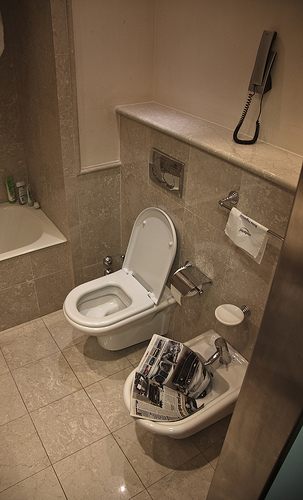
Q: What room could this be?
A: It is a bathroom.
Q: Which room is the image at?
A: It is at the bathroom.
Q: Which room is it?
A: It is a bathroom.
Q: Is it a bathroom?
A: Yes, it is a bathroom.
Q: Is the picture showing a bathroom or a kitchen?
A: It is showing a bathroom.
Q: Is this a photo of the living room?
A: No, the picture is showing the bathroom.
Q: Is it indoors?
A: Yes, it is indoors.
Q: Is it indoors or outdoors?
A: It is indoors.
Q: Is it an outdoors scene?
A: No, it is indoors.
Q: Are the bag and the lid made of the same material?
A: Yes, both the bag and the lid are made of plastic.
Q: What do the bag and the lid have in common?
A: The material, both the bag and the lid are plastic.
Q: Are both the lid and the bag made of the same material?
A: Yes, both the lid and the bag are made of plastic.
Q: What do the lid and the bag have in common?
A: The material, both the lid and the bag are plastic.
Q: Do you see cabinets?
A: No, there are no cabinets.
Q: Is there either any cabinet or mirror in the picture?
A: No, there are no cabinets or mirrors.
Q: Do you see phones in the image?
A: Yes, there is a phone.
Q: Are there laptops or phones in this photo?
A: Yes, there is a phone.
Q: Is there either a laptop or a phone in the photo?
A: Yes, there is a phone.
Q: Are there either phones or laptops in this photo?
A: Yes, there is a phone.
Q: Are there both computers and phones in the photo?
A: No, there is a phone but no computers.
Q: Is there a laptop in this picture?
A: No, there are no laptops.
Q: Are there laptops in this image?
A: No, there are no laptops.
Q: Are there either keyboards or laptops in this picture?
A: No, there are no laptops or keyboards.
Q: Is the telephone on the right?
A: Yes, the telephone is on the right of the image.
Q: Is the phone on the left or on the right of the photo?
A: The phone is on the right of the image.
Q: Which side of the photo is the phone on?
A: The phone is on the right of the image.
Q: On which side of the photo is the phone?
A: The phone is on the right of the image.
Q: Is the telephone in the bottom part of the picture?
A: No, the telephone is in the top of the image.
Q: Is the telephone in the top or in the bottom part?
A: The telephone is in the top of the image.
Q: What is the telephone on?
A: The telephone is on the wall.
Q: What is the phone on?
A: The telephone is on the wall.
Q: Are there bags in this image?
A: Yes, there is a bag.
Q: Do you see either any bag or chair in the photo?
A: Yes, there is a bag.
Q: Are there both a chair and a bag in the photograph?
A: No, there is a bag but no chairs.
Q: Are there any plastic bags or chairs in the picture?
A: Yes, there is a plastic bag.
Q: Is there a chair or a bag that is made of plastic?
A: Yes, the bag is made of plastic.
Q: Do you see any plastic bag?
A: Yes, there is a bag that is made of plastic.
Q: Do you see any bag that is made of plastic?
A: Yes, there is a bag that is made of plastic.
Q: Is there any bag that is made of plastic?
A: Yes, there is a bag that is made of plastic.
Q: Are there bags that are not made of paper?
A: Yes, there is a bag that is made of plastic.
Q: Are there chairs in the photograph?
A: No, there are no chairs.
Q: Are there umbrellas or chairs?
A: No, there are no chairs or umbrellas.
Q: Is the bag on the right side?
A: Yes, the bag is on the right of the image.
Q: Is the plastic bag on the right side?
A: Yes, the bag is on the right of the image.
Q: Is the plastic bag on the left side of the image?
A: No, the bag is on the right of the image.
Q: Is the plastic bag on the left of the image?
A: No, the bag is on the right of the image.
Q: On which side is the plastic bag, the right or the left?
A: The bag is on the right of the image.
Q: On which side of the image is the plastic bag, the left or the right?
A: The bag is on the right of the image.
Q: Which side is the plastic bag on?
A: The bag is on the right of the image.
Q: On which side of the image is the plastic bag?
A: The bag is on the right of the image.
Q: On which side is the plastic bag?
A: The bag is on the right of the image.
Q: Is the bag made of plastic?
A: Yes, the bag is made of plastic.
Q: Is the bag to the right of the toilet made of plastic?
A: Yes, the bag is made of plastic.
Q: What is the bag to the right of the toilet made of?
A: The bag is made of plastic.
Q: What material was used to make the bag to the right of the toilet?
A: The bag is made of plastic.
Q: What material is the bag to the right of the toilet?
A: The bag is made of plastic.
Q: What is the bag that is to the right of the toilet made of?
A: The bag is made of plastic.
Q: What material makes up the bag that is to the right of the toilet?
A: The bag is made of plastic.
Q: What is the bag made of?
A: The bag is made of plastic.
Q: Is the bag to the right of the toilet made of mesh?
A: No, the bag is made of plastic.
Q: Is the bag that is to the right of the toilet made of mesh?
A: No, the bag is made of plastic.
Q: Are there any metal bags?
A: No, there is a bag but it is made of plastic.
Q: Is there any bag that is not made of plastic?
A: No, there is a bag but it is made of plastic.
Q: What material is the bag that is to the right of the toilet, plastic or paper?
A: The bag is made of plastic.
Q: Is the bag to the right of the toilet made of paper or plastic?
A: The bag is made of plastic.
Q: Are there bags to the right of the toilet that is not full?
A: Yes, there is a bag to the right of the toilet.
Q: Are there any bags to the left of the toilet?
A: No, the bag is to the right of the toilet.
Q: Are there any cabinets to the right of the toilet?
A: No, there is a bag to the right of the toilet.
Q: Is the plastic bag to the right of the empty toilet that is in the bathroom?
A: Yes, the bag is to the right of the toilet.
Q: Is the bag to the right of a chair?
A: No, the bag is to the right of the toilet.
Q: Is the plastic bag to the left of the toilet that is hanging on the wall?
A: No, the bag is to the right of the toilet.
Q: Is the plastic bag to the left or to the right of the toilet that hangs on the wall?
A: The bag is to the right of the toilet.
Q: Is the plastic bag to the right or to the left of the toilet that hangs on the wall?
A: The bag is to the right of the toilet.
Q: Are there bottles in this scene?
A: Yes, there is a bottle.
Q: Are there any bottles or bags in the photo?
A: Yes, there is a bottle.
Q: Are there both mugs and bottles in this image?
A: No, there is a bottle but no mugs.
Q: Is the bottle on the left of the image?
A: Yes, the bottle is on the left of the image.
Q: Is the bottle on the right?
A: No, the bottle is on the left of the image.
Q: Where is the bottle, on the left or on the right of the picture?
A: The bottle is on the left of the image.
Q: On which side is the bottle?
A: The bottle is on the left of the image.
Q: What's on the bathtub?
A: The bottle is on the bathtub.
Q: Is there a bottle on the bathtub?
A: Yes, there is a bottle on the bathtub.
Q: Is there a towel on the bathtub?
A: No, there is a bottle on the bathtub.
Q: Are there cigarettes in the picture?
A: No, there are no cigarettes.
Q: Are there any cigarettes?
A: No, there are no cigarettes.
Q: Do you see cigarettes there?
A: No, there are no cigarettes.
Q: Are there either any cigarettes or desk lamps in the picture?
A: No, there are no cigarettes or desk lamps.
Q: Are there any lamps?
A: No, there are no lamps.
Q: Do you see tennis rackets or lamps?
A: No, there are no lamps or tennis rackets.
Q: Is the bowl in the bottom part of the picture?
A: Yes, the bowl is in the bottom of the image.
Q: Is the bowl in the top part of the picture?
A: No, the bowl is in the bottom of the image.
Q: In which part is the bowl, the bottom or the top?
A: The bowl is in the bottom of the image.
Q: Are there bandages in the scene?
A: No, there are no bandages.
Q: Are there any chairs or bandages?
A: No, there are no bandages or chairs.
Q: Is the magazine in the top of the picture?
A: No, the magazine is in the bottom of the image.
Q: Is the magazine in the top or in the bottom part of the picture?
A: The magazine is in the bottom of the image.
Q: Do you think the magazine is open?
A: Yes, the magazine is open.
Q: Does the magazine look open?
A: Yes, the magazine is open.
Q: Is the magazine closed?
A: No, the magazine is open.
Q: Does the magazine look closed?
A: No, the magazine is open.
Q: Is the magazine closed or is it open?
A: The magazine is open.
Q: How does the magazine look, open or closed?
A: The magazine is open.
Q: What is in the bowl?
A: The magazine is in the bowl.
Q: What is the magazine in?
A: The magazine is in the bowl.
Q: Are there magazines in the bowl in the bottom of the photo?
A: Yes, there is a magazine in the bowl.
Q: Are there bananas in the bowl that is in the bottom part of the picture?
A: No, there is a magazine in the bowl.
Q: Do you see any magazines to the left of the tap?
A: Yes, there is a magazine to the left of the tap.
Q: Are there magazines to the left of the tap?
A: Yes, there is a magazine to the left of the tap.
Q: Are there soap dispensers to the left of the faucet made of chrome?
A: No, there is a magazine to the left of the tap.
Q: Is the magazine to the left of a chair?
A: No, the magazine is to the left of the faucet.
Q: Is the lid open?
A: Yes, the lid is open.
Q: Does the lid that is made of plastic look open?
A: Yes, the lid is open.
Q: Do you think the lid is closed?
A: No, the lid is open.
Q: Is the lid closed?
A: No, the lid is open.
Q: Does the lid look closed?
A: No, the lid is open.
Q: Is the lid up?
A: Yes, the lid is up.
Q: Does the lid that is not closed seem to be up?
A: Yes, the lid is up.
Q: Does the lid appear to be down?
A: No, the lid is up.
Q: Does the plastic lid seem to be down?
A: No, the lid is up.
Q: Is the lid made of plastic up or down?
A: The lid is up.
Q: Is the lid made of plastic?
A: Yes, the lid is made of plastic.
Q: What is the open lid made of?
A: The lid is made of plastic.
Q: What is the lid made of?
A: The lid is made of plastic.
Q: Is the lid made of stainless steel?
A: No, the lid is made of plastic.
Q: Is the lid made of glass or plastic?
A: The lid is made of plastic.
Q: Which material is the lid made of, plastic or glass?
A: The lid is made of plastic.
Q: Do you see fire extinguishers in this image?
A: No, there are no fire extinguishers.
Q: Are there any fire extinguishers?
A: No, there are no fire extinguishers.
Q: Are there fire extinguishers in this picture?
A: No, there are no fire extinguishers.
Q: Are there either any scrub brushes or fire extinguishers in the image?
A: No, there are no fire extinguishers or scrub brushes.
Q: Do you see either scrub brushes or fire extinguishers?
A: No, there are no fire extinguishers or scrub brushes.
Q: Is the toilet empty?
A: Yes, the toilet is empty.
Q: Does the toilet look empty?
A: Yes, the toilet is empty.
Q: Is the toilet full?
A: No, the toilet is empty.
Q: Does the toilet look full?
A: No, the toilet is empty.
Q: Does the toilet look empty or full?
A: The toilet is empty.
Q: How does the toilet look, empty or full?
A: The toilet is empty.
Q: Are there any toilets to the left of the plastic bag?
A: Yes, there is a toilet to the left of the bag.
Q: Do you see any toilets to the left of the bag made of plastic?
A: Yes, there is a toilet to the left of the bag.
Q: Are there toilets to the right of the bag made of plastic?
A: No, the toilet is to the left of the bag.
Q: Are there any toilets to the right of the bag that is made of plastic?
A: No, the toilet is to the left of the bag.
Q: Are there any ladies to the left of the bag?
A: No, there is a toilet to the left of the bag.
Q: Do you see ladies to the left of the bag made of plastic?
A: No, there is a toilet to the left of the bag.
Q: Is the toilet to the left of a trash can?
A: No, the toilet is to the left of the bag.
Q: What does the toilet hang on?
A: The toilet hangs on the wall.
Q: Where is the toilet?
A: The toilet is in the bathroom.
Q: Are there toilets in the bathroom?
A: Yes, there is a toilet in the bathroom.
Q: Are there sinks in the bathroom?
A: No, there is a toilet in the bathroom.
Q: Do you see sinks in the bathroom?
A: No, there is a toilet in the bathroom.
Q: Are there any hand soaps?
A: No, there are no hand soaps.